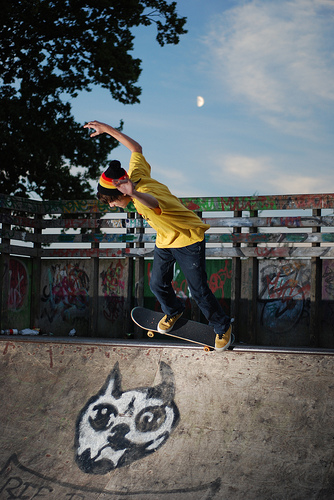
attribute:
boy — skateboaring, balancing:
[84, 119, 235, 356]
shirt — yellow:
[124, 151, 209, 247]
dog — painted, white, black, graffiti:
[70, 360, 186, 475]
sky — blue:
[6, 5, 333, 260]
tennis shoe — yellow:
[212, 326, 235, 353]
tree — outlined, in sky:
[2, 3, 189, 234]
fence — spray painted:
[3, 194, 333, 355]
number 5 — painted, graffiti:
[260, 261, 306, 337]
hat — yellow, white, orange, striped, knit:
[92, 159, 129, 197]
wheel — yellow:
[201, 347, 210, 355]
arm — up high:
[111, 174, 162, 210]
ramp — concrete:
[1, 331, 333, 500]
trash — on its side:
[5, 324, 18, 339]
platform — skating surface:
[4, 323, 330, 354]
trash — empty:
[19, 324, 46, 336]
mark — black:
[77, 353, 90, 365]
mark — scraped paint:
[41, 345, 62, 368]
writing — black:
[4, 469, 86, 500]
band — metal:
[4, 338, 334, 363]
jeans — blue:
[146, 246, 229, 338]